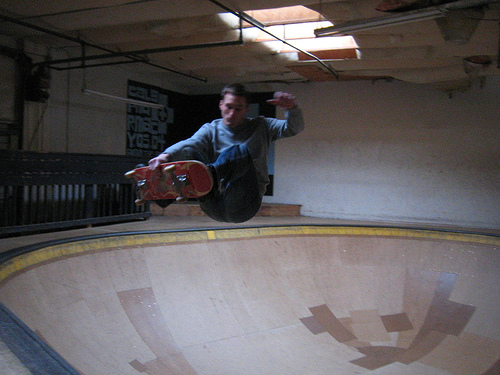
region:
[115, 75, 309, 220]
a man doing a skateboard trick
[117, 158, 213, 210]
a red skateboard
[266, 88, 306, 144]
an arm of a person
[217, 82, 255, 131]
the head of a person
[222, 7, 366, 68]
light from a ceiling window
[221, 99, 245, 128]
the face of a person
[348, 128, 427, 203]
a white brick wall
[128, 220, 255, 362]
a skateboard ramp for tricks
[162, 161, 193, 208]
wheels of a skateboard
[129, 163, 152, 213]
wheels of a skateboard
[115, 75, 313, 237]
a skateboarder in the air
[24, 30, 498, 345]
a skate rink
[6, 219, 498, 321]
a yellow line on outer curb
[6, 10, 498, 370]
the inside of a skatepark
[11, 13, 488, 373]
a scene happening inside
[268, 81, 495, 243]
a white wall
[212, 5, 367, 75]
light shining through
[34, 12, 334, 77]
some silver pipes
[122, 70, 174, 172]
a black and white poster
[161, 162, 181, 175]
the front right wheel of the skateboard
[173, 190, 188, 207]
the front left wheel of the skateboard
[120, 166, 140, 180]
the back right wheel of the skateboard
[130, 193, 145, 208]
the back left wheel on the skateboard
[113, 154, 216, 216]
a red skateboard in mid air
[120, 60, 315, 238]
a man on a skateboard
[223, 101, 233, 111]
the man's right eye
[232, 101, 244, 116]
the man's left eye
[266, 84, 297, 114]
the man's left hand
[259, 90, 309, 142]
the man's left arm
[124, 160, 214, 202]
large red colored skateboard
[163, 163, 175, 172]
small white colored wheel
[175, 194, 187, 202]
small white colored wheel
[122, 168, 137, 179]
small white colored wheel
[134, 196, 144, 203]
small white colored wheel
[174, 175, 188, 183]
metal silver skateboard part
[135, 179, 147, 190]
metal silver skateboard part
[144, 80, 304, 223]
man doing jump on skateboard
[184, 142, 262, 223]
dark colored blue jeans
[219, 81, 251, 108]
short dark brown hair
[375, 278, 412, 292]
part of a lamp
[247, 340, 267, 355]
part of a court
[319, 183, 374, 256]
edge of a court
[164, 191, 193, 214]
part of a wheel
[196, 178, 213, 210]
edge of a board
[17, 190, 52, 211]
part of a rail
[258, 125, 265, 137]
part of a sweater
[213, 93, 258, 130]
face of a man